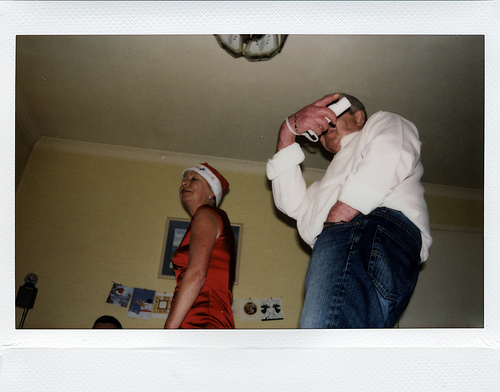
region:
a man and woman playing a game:
[141, 85, 436, 322]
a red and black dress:
[165, 205, 240, 331]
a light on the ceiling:
[215, 31, 300, 57]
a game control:
[300, 95, 345, 140]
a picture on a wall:
[150, 215, 181, 281]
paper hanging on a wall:
[245, 296, 286, 322]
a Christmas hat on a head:
[183, 157, 229, 205]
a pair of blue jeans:
[299, 208, 429, 324]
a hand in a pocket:
[316, 200, 351, 260]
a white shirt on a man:
[265, 114, 440, 250]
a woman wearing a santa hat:
[151, 142, 258, 253]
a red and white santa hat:
[148, 142, 243, 209]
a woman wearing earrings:
[153, 145, 243, 235]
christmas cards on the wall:
[92, 266, 331, 330]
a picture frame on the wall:
[129, 180, 264, 317]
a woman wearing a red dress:
[147, 148, 267, 349]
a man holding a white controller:
[266, 80, 434, 270]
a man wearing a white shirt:
[271, 85, 416, 222]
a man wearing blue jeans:
[273, 88, 469, 385]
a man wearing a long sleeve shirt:
[244, 88, 443, 258]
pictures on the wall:
[96, 268, 290, 330]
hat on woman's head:
[176, 155, 231, 207]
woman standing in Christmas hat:
[136, 153, 243, 348]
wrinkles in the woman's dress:
[195, 239, 227, 344]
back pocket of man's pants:
[346, 225, 421, 310]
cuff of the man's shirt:
[260, 138, 308, 186]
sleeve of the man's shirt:
[264, 139, 311, 229]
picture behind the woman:
[150, 205, 248, 306]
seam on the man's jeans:
[312, 208, 377, 331]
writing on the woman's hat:
[183, 163, 214, 172]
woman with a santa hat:
[165, 153, 247, 331]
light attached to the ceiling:
[207, 29, 294, 64]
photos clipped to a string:
[102, 277, 296, 326]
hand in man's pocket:
[316, 192, 361, 229]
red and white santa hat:
[177, 158, 232, 204]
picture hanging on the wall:
[161, 208, 247, 290]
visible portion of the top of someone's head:
[88, 307, 123, 332]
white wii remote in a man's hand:
[273, 93, 354, 151]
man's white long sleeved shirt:
[267, 107, 439, 268]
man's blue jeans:
[297, 193, 425, 327]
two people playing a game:
[165, 78, 435, 323]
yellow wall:
[13, 143, 491, 335]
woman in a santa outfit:
[158, 149, 249, 334]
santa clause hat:
[182, 156, 232, 205]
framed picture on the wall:
[156, 205, 251, 288]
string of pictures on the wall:
[101, 272, 296, 324]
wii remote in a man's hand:
[277, 90, 356, 146]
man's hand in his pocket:
[319, 183, 363, 254]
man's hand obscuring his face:
[279, 88, 355, 151]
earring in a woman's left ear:
[206, 193, 213, 197]